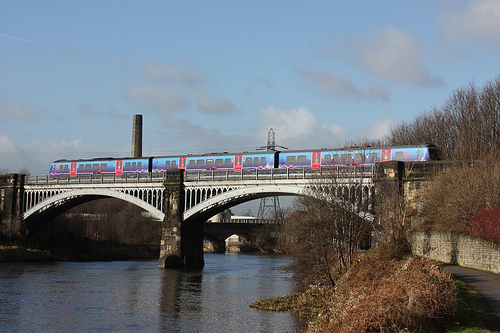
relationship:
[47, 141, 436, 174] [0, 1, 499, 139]
train below sky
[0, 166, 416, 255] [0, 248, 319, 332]
bridge above water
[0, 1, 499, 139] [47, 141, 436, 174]
sky above train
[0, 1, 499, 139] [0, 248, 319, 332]
sky above water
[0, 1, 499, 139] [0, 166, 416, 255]
sky above bridge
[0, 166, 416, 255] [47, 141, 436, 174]
bridge below train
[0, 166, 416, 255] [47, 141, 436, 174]
bridge under train